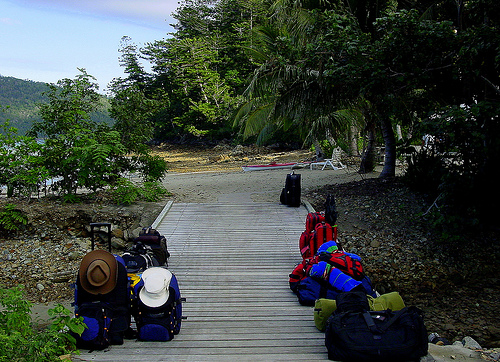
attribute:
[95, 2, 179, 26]
clouds — distant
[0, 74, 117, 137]
hill — green, distant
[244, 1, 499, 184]
tree — brown, palm, green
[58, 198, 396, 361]
sidewalk — wooden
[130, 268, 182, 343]
bag — blue, black, beneath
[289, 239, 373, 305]
luggage — blue, travelors, black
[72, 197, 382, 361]
walkways — wooden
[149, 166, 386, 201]
beach — sandy, lounging, rocky, line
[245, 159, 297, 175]
canoe — sort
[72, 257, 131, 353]
backpack — black, blue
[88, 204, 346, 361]
bridge — wooden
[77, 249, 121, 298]
hat — brown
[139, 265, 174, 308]
hat — white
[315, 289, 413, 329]
bag — green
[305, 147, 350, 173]
chaise — lounge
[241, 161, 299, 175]
boat — red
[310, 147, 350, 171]
chair — beach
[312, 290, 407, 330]
roll — green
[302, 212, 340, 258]
bag — red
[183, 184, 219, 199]
sand — brown